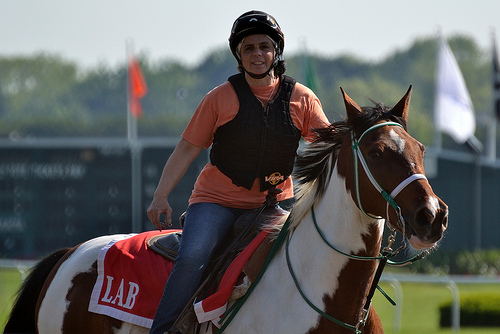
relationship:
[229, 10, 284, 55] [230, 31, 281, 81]
helmet on head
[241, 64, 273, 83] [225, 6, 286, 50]
chin strap of helmet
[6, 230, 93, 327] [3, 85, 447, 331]
black tail of horse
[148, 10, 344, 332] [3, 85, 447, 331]
woman riding a horse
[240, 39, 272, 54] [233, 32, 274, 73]
glasses on face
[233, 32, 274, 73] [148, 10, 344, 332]
face of woman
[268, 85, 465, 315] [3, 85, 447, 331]
bridal on horse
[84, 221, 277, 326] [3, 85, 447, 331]
blanket on horse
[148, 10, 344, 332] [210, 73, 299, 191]
woman wearing black vest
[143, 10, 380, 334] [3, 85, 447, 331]
man riding a horse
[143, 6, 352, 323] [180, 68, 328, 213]
man wearing shirt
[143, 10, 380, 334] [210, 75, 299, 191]
man wearing black vest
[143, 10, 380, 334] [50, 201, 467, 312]
man on horse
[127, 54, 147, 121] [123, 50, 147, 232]
flag on pole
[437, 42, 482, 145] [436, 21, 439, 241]
flag on pole